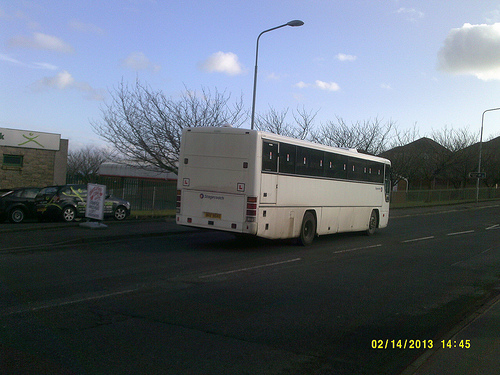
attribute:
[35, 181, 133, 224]
hybrid — green